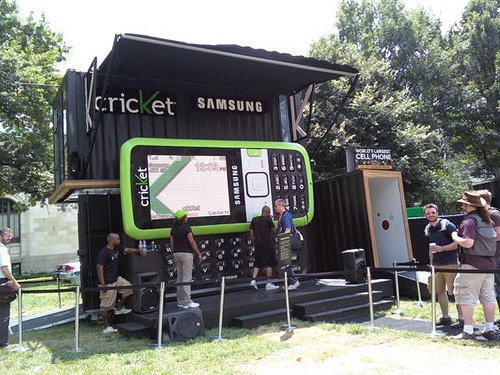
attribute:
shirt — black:
[93, 245, 133, 287]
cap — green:
[173, 206, 192, 221]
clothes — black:
[248, 215, 278, 267]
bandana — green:
[171, 207, 186, 221]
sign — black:
[90, 88, 175, 119]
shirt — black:
[168, 219, 195, 254]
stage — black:
[118, 275, 385, 327]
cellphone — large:
[113, 131, 318, 230]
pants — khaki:
[98, 274, 132, 309]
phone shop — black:
[42, 27, 422, 335]